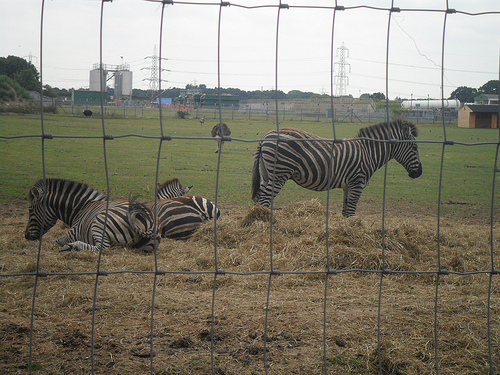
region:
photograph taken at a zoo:
[24, 9, 469, 350]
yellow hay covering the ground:
[37, 221, 419, 350]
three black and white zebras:
[16, 114, 453, 242]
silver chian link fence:
[20, 26, 475, 351]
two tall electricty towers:
[141, 32, 367, 90]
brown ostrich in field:
[200, 119, 239, 152]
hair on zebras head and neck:
[358, 113, 419, 140]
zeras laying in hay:
[23, 167, 213, 252]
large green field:
[4, 116, 499, 191]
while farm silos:
[82, 66, 135, 101]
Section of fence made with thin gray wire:
[321, 2, 498, 107]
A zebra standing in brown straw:
[253, 112, 425, 219]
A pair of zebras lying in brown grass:
[23, 175, 207, 260]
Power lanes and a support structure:
[334, 41, 382, 91]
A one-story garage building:
[453, 103, 499, 131]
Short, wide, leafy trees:
[8, 52, 36, 95]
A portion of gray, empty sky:
[228, 11, 271, 53]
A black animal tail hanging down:
[246, 152, 263, 204]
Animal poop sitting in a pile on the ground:
[167, 327, 209, 354]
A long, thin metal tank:
[399, 96, 444, 116]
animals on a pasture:
[6, 120, 462, 361]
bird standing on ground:
[203, 119, 238, 153]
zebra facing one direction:
[233, 125, 442, 219]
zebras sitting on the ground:
[12, 143, 234, 264]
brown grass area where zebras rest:
[5, 187, 487, 368]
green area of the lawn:
[6, 116, 471, 207]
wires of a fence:
[1, 8, 479, 340]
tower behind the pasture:
[320, 35, 356, 98]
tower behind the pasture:
[131, 46, 171, 102]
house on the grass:
[456, 103, 494, 130]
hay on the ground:
[296, 226, 366, 281]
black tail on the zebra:
[248, 139, 264, 198]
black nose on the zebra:
[411, 160, 427, 176]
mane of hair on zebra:
[358, 120, 414, 128]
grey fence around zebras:
[16, 11, 497, 371]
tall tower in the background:
[330, 36, 352, 99]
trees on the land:
[1, 52, 40, 100]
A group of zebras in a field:
[20, 117, 420, 278]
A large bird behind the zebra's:
[186, 116, 237, 181]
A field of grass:
[73, 123, 285, 192]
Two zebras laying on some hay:
[31, 183, 191, 257]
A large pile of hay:
[261, 204, 436, 294]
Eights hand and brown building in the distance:
[421, 101, 492, 151]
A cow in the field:
[59, 103, 102, 137]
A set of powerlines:
[75, 40, 375, 110]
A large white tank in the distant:
[343, 86, 464, 106]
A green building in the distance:
[173, 89, 238, 115]